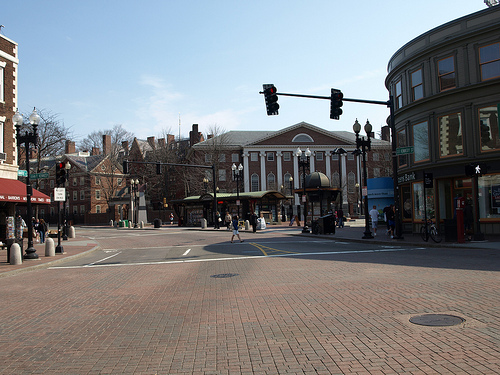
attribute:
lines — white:
[106, 246, 243, 273]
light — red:
[259, 82, 284, 122]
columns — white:
[238, 140, 351, 202]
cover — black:
[409, 312, 465, 327]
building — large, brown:
[190, 120, 392, 218]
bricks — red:
[102, 290, 353, 371]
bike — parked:
[417, 217, 442, 245]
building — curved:
[383, 5, 492, 249]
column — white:
[241, 160, 254, 185]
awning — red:
[0, 176, 52, 203]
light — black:
[328, 88, 345, 123]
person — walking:
[35, 216, 50, 246]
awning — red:
[3, 164, 70, 236]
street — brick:
[168, 222, 374, 348]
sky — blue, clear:
[73, 12, 225, 83]